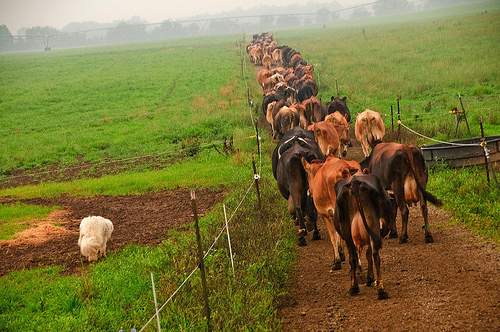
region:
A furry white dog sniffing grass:
[73, 212, 113, 262]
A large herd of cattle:
[245, 30, 432, 310]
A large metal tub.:
[417, 130, 492, 175]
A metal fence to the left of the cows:
[122, 130, 262, 325]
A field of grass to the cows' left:
[0, 35, 237, 141]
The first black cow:
[330, 170, 385, 297]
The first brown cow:
[297, 151, 362, 276]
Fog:
[1, 0, 401, 50]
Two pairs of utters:
[347, 169, 427, 261]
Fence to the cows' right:
[382, 96, 497, 246]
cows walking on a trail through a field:
[28, 3, 494, 315]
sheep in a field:
[59, 200, 120, 305]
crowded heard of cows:
[241, 8, 454, 279]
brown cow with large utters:
[335, 173, 383, 292]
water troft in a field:
[412, 130, 491, 170]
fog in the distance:
[13, 3, 490, 56]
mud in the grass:
[116, 173, 215, 285]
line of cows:
[248, 35, 325, 149]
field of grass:
[318, 31, 495, 91]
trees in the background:
[3, 13, 482, 52]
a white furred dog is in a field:
[72, 211, 115, 264]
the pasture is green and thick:
[5, 20, 496, 180]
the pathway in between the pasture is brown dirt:
[246, 30, 493, 330]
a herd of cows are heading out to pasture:
[243, 25, 445, 302]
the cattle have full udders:
[332, 150, 437, 298]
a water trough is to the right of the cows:
[420, 130, 496, 170]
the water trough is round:
[422, 132, 497, 168]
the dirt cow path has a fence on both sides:
[138, 46, 485, 326]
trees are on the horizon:
[5, 5, 497, 36]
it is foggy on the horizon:
[8, 2, 496, 49]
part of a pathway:
[431, 258, 476, 308]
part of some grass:
[98, 280, 138, 307]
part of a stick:
[173, 222, 220, 299]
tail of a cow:
[355, 214, 390, 247]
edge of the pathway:
[280, 230, 301, 277]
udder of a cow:
[348, 226, 366, 256]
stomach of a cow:
[307, 180, 323, 198]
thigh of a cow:
[394, 162, 406, 183]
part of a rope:
[426, 131, 474, 167]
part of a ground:
[148, 195, 198, 215]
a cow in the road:
[335, 170, 392, 298]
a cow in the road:
[363, 138, 440, 245]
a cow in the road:
[303, 153, 363, 275]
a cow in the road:
[278, 133, 323, 248]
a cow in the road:
[307, 115, 336, 162]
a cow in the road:
[347, 103, 384, 161]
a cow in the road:
[326, 90, 348, 119]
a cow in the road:
[327, 107, 352, 149]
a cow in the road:
[301, 91, 326, 121]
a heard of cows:
[243, 15, 441, 302]